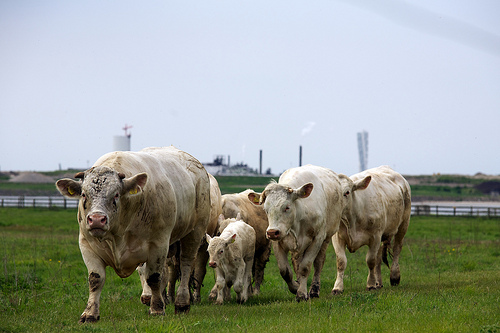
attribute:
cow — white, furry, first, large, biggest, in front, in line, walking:
[54, 144, 213, 325]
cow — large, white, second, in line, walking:
[249, 163, 344, 303]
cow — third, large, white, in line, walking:
[331, 164, 413, 297]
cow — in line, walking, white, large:
[208, 189, 273, 301]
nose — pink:
[86, 213, 109, 230]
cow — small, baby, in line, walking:
[204, 219, 256, 303]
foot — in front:
[214, 298, 225, 305]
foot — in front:
[235, 295, 246, 305]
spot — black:
[82, 197, 89, 210]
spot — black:
[88, 271, 102, 280]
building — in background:
[200, 155, 277, 177]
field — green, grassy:
[1, 206, 499, 331]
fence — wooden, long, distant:
[0, 195, 499, 219]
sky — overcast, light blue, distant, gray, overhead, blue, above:
[1, 2, 499, 178]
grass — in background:
[0, 174, 499, 202]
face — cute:
[206, 245, 226, 269]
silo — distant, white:
[112, 123, 134, 152]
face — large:
[79, 188, 123, 237]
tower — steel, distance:
[355, 129, 370, 173]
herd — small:
[54, 143, 413, 324]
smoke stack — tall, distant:
[258, 150, 263, 174]